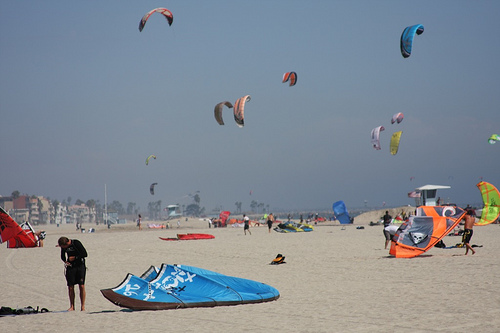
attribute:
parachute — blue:
[102, 261, 278, 309]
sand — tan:
[10, 211, 499, 330]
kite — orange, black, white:
[231, 93, 253, 129]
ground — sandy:
[1, 214, 498, 331]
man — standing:
[443, 202, 494, 265]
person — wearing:
[48, 231, 98, 316]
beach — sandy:
[304, 245, 428, 320]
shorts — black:
[66, 260, 85, 285]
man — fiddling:
[58, 237, 90, 311]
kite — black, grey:
[211, 98, 234, 128]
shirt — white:
[385, 222, 401, 240]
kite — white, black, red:
[279, 70, 301, 91]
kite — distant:
[112, 124, 184, 211]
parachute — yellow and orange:
[464, 166, 498, 229]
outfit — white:
[240, 211, 257, 237]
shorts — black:
[62, 259, 91, 288]